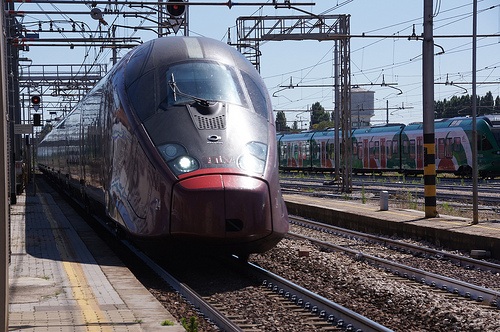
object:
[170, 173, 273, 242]
red paint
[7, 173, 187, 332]
brick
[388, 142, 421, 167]
ground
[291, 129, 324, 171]
ground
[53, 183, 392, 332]
track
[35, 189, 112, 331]
line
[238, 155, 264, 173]
headlight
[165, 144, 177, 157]
headlight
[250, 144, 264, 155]
headlight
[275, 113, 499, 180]
train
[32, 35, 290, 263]
train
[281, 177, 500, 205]
track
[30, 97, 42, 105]
light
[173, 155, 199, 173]
headlight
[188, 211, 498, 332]
pebbles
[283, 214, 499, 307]
track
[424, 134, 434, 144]
stripe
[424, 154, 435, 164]
stripe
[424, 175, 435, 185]
stripe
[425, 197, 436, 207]
stripe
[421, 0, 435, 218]
pole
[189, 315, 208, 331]
weeds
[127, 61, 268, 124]
windshield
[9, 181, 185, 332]
platform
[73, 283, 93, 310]
paint